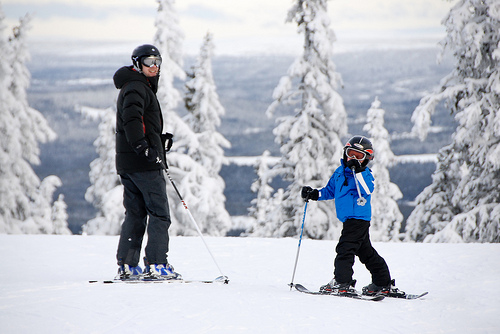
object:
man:
[113, 44, 184, 283]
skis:
[102, 274, 230, 286]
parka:
[317, 163, 376, 221]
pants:
[116, 165, 174, 266]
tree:
[408, 0, 499, 242]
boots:
[141, 258, 184, 281]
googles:
[346, 147, 373, 162]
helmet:
[342, 134, 374, 168]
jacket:
[112, 65, 170, 174]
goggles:
[131, 55, 163, 67]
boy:
[302, 136, 395, 297]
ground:
[0, 233, 499, 332]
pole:
[156, 156, 232, 283]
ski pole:
[287, 186, 312, 291]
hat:
[129, 44, 161, 66]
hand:
[347, 159, 361, 172]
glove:
[302, 185, 319, 200]